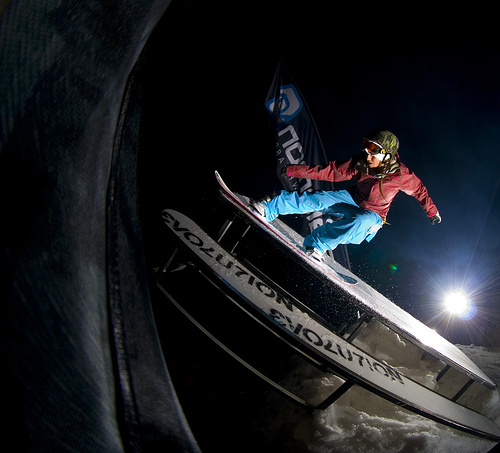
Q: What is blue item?
A: Pants.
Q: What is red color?
A: Jacket.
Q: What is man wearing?
A: Gloves.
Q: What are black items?
A: Gloves.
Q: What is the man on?
A: Snowboard.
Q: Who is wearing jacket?
A: The man.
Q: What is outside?
A: Bench.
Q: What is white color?
A: Bench.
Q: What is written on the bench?
A: Evolution.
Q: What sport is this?
A: Snowboarding.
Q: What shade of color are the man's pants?
A: Blue.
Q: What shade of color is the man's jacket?
A: Red.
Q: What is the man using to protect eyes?
A: Goggles.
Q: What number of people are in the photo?
A: 1.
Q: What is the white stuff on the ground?
A: Snow.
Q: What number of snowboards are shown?
A: 1.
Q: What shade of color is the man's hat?
A: Green.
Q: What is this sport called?
A: Snowboarding.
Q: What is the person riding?
A: Snowboard.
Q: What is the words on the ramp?
A: Revolution.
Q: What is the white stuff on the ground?
A: Snow.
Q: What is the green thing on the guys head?
A: Helmet.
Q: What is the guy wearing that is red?
A: Jacket.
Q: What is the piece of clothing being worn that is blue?
A: Pants.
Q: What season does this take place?
A: Winter.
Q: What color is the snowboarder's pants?
A: Blue.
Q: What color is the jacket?
A: Red.